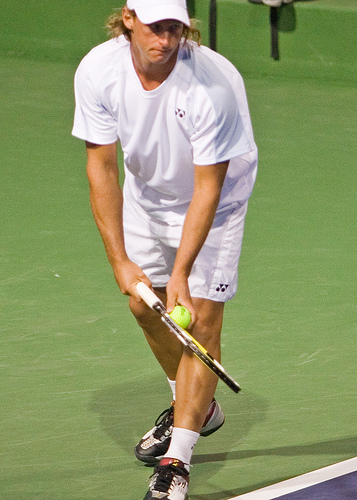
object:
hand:
[109, 258, 154, 302]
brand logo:
[213, 282, 228, 292]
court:
[0, 0, 357, 499]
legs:
[128, 286, 236, 497]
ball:
[168, 305, 192, 328]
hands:
[163, 275, 203, 337]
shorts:
[75, 185, 270, 293]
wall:
[1, 4, 353, 85]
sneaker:
[142, 458, 190, 499]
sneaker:
[132, 394, 226, 463]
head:
[122, 0, 185, 70]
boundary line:
[230, 455, 355, 499]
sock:
[163, 424, 202, 464]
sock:
[165, 375, 178, 402]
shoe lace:
[153, 464, 182, 488]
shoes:
[134, 397, 225, 497]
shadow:
[86, 367, 356, 499]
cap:
[125, 0, 191, 29]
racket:
[132, 280, 245, 395]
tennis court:
[2, 0, 357, 499]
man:
[70, 0, 259, 497]